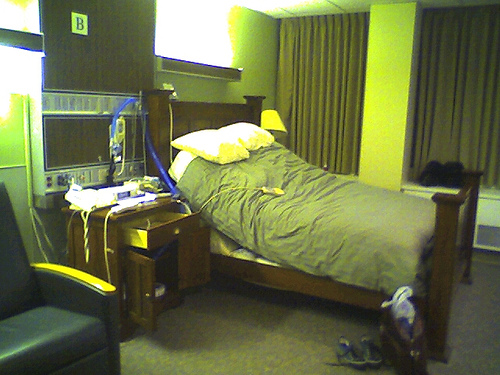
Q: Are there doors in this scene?
A: Yes, there is a door.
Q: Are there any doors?
A: Yes, there is a door.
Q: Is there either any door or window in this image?
A: Yes, there is a door.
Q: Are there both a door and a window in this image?
A: Yes, there are both a door and a window.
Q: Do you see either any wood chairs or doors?
A: Yes, there is a wood door.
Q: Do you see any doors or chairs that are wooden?
A: Yes, the door is wooden.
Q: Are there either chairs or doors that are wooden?
A: Yes, the door is wooden.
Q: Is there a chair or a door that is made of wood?
A: Yes, the door is made of wood.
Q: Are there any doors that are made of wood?
A: Yes, there is a door that is made of wood.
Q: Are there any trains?
A: No, there are no trains.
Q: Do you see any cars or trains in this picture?
A: No, there are no trains or cars.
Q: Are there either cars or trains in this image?
A: No, there are no trains or cars.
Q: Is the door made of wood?
A: Yes, the door is made of wood.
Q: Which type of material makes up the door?
A: The door is made of wood.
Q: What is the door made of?
A: The door is made of wood.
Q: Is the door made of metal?
A: No, the door is made of wood.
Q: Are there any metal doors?
A: No, there is a door but it is made of wood.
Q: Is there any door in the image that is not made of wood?
A: No, there is a door but it is made of wood.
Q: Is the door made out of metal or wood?
A: The door is made of wood.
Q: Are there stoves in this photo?
A: No, there are no stoves.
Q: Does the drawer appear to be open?
A: Yes, the drawer is open.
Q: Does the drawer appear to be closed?
A: No, the drawer is open.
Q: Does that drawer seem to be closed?
A: No, the drawer is open.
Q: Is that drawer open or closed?
A: The drawer is open.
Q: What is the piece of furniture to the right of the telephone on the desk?
A: The piece of furniture is a drawer.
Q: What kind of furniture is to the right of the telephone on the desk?
A: The piece of furniture is a drawer.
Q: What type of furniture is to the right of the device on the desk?
A: The piece of furniture is a drawer.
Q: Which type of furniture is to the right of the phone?
A: The piece of furniture is a drawer.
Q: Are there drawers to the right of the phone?
A: Yes, there is a drawer to the right of the phone.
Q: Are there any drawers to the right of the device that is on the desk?
A: Yes, there is a drawer to the right of the phone.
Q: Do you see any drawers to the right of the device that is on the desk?
A: Yes, there is a drawer to the right of the phone.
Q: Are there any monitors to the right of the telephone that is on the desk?
A: No, there is a drawer to the right of the phone.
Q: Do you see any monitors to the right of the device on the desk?
A: No, there is a drawer to the right of the phone.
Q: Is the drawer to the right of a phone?
A: Yes, the drawer is to the right of a phone.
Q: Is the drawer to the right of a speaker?
A: No, the drawer is to the right of a phone.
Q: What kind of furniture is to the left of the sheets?
A: The piece of furniture is a drawer.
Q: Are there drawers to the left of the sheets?
A: Yes, there is a drawer to the left of the sheets.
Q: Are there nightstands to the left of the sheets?
A: No, there is a drawer to the left of the sheets.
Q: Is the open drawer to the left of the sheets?
A: Yes, the drawer is to the left of the sheets.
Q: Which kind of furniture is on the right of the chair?
A: The piece of furniture is a drawer.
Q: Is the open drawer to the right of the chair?
A: Yes, the drawer is to the right of the chair.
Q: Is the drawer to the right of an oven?
A: No, the drawer is to the right of the chair.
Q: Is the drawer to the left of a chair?
A: No, the drawer is to the right of a chair.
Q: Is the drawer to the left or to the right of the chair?
A: The drawer is to the right of the chair.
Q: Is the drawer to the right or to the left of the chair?
A: The drawer is to the right of the chair.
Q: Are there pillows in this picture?
A: Yes, there is a pillow.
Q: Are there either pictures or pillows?
A: Yes, there is a pillow.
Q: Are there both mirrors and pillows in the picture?
A: No, there is a pillow but no mirrors.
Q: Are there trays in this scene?
A: No, there are no trays.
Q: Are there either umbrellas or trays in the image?
A: No, there are no trays or umbrellas.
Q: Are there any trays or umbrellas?
A: No, there are no trays or umbrellas.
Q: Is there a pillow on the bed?
A: Yes, there is a pillow on the bed.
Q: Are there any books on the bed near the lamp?
A: No, there is a pillow on the bed.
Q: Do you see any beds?
A: Yes, there is a bed.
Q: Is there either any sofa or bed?
A: Yes, there is a bed.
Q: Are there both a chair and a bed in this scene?
A: Yes, there are both a bed and a chair.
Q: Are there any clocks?
A: No, there are no clocks.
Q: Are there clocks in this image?
A: No, there are no clocks.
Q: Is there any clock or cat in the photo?
A: No, there are no clocks or cats.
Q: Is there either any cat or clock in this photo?
A: No, there are no clocks or cats.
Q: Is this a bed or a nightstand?
A: This is a bed.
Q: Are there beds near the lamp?
A: Yes, there is a bed near the lamp.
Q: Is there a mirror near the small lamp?
A: No, there is a bed near the lamp.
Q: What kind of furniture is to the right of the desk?
A: The piece of furniture is a bed.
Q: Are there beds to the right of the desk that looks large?
A: Yes, there is a bed to the right of the desk.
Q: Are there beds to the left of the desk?
A: No, the bed is to the right of the desk.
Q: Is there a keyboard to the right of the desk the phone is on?
A: No, there is a bed to the right of the desk.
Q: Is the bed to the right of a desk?
A: Yes, the bed is to the right of a desk.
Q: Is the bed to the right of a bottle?
A: No, the bed is to the right of a desk.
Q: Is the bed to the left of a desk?
A: No, the bed is to the right of a desk.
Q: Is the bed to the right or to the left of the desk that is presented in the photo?
A: The bed is to the right of the desk.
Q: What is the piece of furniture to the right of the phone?
A: The piece of furniture is a bed.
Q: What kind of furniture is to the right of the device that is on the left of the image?
A: The piece of furniture is a bed.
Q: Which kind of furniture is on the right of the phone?
A: The piece of furniture is a bed.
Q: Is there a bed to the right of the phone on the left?
A: Yes, there is a bed to the right of the telephone.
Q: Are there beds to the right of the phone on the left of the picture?
A: Yes, there is a bed to the right of the telephone.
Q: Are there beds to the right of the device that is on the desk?
A: Yes, there is a bed to the right of the telephone.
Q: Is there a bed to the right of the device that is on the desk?
A: Yes, there is a bed to the right of the telephone.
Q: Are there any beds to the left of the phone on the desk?
A: No, the bed is to the right of the phone.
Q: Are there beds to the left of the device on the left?
A: No, the bed is to the right of the phone.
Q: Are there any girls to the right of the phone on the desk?
A: No, there is a bed to the right of the telephone.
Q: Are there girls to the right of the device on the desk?
A: No, there is a bed to the right of the telephone.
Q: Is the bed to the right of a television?
A: No, the bed is to the right of a phone.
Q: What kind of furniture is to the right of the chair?
A: The piece of furniture is a bed.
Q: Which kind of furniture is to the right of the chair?
A: The piece of furniture is a bed.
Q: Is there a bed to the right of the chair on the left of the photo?
A: Yes, there is a bed to the right of the chair.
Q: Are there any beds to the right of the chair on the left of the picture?
A: Yes, there is a bed to the right of the chair.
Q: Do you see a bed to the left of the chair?
A: No, the bed is to the right of the chair.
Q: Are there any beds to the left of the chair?
A: No, the bed is to the right of the chair.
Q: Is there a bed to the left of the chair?
A: No, the bed is to the right of the chair.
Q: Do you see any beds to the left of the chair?
A: No, the bed is to the right of the chair.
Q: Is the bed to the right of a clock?
A: No, the bed is to the right of the chair.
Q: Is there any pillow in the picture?
A: Yes, there are pillows.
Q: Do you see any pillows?
A: Yes, there are pillows.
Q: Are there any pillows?
A: Yes, there are pillows.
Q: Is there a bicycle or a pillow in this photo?
A: Yes, there are pillows.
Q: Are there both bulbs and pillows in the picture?
A: No, there are pillows but no light bulbs.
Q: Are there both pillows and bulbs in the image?
A: No, there are pillows but no light bulbs.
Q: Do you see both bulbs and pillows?
A: No, there are pillows but no light bulbs.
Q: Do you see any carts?
A: No, there are no carts.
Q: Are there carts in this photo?
A: No, there are no carts.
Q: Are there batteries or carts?
A: No, there are no carts or batteries.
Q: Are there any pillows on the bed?
A: Yes, there are pillows on the bed.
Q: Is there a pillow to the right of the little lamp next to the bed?
A: Yes, there are pillows to the right of the lamp.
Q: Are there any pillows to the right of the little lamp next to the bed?
A: Yes, there are pillows to the right of the lamp.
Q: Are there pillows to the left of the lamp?
A: No, the pillows are to the right of the lamp.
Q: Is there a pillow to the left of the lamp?
A: No, the pillows are to the right of the lamp.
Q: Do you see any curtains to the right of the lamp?
A: No, there are pillows to the right of the lamp.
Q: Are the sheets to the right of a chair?
A: Yes, the sheets are to the right of a chair.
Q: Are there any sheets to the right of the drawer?
A: Yes, there are sheets to the right of the drawer.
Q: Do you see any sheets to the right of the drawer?
A: Yes, there are sheets to the right of the drawer.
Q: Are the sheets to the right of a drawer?
A: Yes, the sheets are to the right of a drawer.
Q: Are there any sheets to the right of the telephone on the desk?
A: Yes, there are sheets to the right of the phone.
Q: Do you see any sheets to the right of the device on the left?
A: Yes, there are sheets to the right of the phone.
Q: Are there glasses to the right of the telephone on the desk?
A: No, there are sheets to the right of the telephone.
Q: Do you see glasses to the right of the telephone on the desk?
A: No, there are sheets to the right of the telephone.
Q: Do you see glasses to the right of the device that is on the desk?
A: No, there are sheets to the right of the telephone.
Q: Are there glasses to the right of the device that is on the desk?
A: No, there are sheets to the right of the telephone.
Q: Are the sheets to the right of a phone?
A: Yes, the sheets are to the right of a phone.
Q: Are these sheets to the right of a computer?
A: No, the sheets are to the right of a phone.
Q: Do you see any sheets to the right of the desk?
A: Yes, there are sheets to the right of the desk.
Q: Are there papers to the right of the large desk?
A: No, there are sheets to the right of the desk.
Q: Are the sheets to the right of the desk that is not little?
A: Yes, the sheets are to the right of the desk.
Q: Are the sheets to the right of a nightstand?
A: No, the sheets are to the right of the desk.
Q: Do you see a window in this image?
A: Yes, there is a window.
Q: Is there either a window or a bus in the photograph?
A: Yes, there is a window.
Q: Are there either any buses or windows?
A: Yes, there is a window.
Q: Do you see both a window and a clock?
A: No, there is a window but no clocks.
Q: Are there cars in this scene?
A: No, there are no cars.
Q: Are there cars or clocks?
A: No, there are no cars or clocks.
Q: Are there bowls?
A: No, there are no bowls.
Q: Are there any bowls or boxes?
A: No, there are no bowls or boxes.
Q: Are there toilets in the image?
A: No, there are no toilets.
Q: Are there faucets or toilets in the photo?
A: No, there are no toilets or faucets.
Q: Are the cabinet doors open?
A: Yes, the cabinet doors are open.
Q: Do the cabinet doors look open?
A: Yes, the cabinet doors are open.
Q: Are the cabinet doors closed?
A: No, the cabinet doors are open.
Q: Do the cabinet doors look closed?
A: No, the cabinet doors are open.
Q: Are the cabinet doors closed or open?
A: The cabinet doors are open.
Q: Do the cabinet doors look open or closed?
A: The cabinet doors are open.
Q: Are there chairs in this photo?
A: Yes, there is a chair.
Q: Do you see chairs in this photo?
A: Yes, there is a chair.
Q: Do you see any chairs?
A: Yes, there is a chair.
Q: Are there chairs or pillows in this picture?
A: Yes, there is a chair.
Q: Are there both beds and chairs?
A: Yes, there are both a chair and beds.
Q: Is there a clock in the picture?
A: No, there are no clocks.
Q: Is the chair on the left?
A: Yes, the chair is on the left of the image.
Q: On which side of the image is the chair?
A: The chair is on the left of the image.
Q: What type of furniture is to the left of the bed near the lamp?
A: The piece of furniture is a chair.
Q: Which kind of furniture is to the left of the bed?
A: The piece of furniture is a chair.